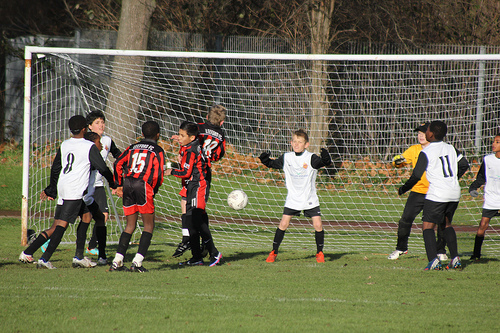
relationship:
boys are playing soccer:
[33, 114, 122, 269] [8, 6, 492, 331]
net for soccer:
[21, 54, 487, 273] [8, 6, 492, 331]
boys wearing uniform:
[107, 121, 167, 274] [122, 138, 153, 269]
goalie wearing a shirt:
[397, 117, 458, 256] [390, 151, 435, 193]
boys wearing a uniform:
[33, 114, 122, 269] [30, 107, 116, 274]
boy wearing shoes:
[238, 130, 347, 265] [255, 245, 337, 289]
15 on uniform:
[120, 152, 153, 183] [122, 138, 153, 269]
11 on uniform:
[425, 145, 461, 199] [416, 123, 463, 274]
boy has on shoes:
[238, 130, 347, 265] [255, 245, 337, 289]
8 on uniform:
[51, 130, 98, 186] [30, 107, 116, 274]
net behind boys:
[21, 54, 487, 273] [33, 114, 122, 269]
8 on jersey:
[51, 130, 98, 186] [40, 139, 110, 207]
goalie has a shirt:
[397, 117, 458, 256] [390, 151, 435, 193]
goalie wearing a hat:
[397, 117, 458, 256] [396, 126, 433, 156]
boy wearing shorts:
[238, 130, 347, 265] [269, 210, 326, 226]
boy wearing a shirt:
[238, 130, 347, 265] [260, 145, 341, 220]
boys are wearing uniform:
[107, 116, 258, 298] [112, 140, 166, 258]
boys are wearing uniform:
[41, 122, 133, 284] [49, 136, 116, 263]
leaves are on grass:
[11, 125, 476, 202] [13, 168, 494, 319]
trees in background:
[59, 11, 491, 143] [3, 5, 483, 76]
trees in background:
[59, 11, 491, 143] [3, 2, 465, 81]